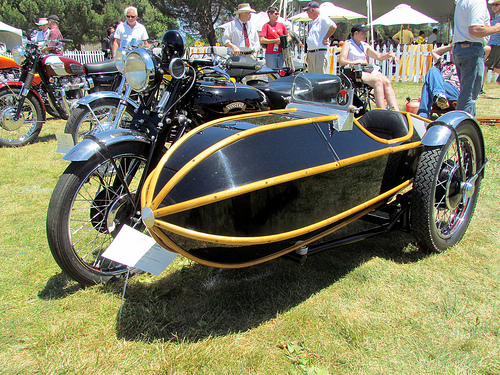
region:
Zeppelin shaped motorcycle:
[35, 40, 481, 317]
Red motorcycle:
[1, 39, 158, 147]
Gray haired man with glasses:
[101, 2, 157, 64]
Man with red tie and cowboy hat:
[208, 0, 270, 68]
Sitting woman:
[336, 23, 411, 124]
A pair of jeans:
[445, 30, 491, 119]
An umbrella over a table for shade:
[366, 5, 441, 46]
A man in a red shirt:
[258, 4, 295, 64]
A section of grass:
[326, 302, 459, 364]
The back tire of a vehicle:
[396, 102, 493, 267]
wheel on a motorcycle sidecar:
[402, 99, 494, 264]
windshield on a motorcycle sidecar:
[276, 61, 361, 136]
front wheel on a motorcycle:
[32, 122, 189, 297]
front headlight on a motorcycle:
[114, 42, 167, 104]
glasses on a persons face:
[123, 12, 139, 20]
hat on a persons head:
[346, 18, 378, 36]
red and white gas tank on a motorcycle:
[32, 48, 89, 83]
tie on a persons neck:
[238, 18, 254, 52]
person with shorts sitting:
[330, 14, 409, 119]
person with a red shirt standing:
[256, 1, 303, 80]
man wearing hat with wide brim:
[220, 0, 268, 79]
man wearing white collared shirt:
[218, 4, 266, 81]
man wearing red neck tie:
[209, 4, 272, 81]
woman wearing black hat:
[336, 13, 406, 124]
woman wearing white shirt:
[332, 18, 412, 115]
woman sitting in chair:
[337, 20, 409, 117]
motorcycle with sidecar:
[49, 31, 489, 323]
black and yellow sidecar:
[142, 87, 495, 274]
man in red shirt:
[256, 2, 302, 80]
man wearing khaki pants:
[299, 0, 337, 100]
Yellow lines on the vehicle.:
[133, 105, 405, 261]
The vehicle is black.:
[225, 111, 403, 217]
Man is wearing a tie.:
[231, 23, 257, 47]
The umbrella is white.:
[366, 0, 448, 36]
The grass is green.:
[320, 291, 457, 366]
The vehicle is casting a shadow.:
[134, 262, 304, 332]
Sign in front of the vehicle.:
[93, 220, 184, 327]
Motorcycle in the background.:
[13, 44, 131, 136]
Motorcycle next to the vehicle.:
[56, 62, 362, 254]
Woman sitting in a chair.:
[334, 24, 409, 107]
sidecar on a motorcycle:
[128, 98, 484, 269]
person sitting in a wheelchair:
[326, 23, 401, 117]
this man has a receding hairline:
[103, 2, 157, 88]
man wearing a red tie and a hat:
[215, 2, 266, 79]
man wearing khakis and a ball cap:
[299, 1, 339, 73]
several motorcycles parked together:
[2, 39, 483, 280]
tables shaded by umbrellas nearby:
[291, 0, 441, 56]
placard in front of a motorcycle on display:
[83, 215, 185, 301]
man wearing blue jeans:
[446, 0, 494, 122]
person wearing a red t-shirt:
[257, 5, 294, 75]